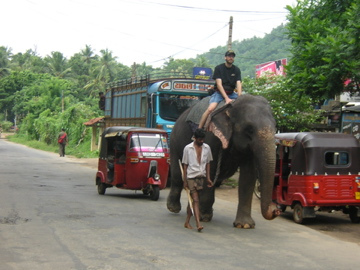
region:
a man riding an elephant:
[163, 46, 278, 239]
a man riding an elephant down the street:
[4, 46, 289, 235]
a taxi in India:
[82, 120, 168, 201]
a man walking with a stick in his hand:
[174, 128, 213, 227]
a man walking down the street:
[49, 123, 85, 167]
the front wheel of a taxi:
[146, 183, 160, 200]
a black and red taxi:
[271, 123, 358, 233]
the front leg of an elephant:
[233, 173, 256, 233]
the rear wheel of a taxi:
[291, 200, 307, 221]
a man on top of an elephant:
[189, 45, 253, 128]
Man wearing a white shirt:
[188, 152, 224, 174]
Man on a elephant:
[204, 51, 241, 100]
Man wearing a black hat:
[220, 43, 240, 63]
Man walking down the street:
[55, 123, 73, 169]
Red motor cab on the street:
[94, 122, 169, 199]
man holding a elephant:
[176, 124, 233, 209]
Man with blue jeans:
[202, 89, 244, 106]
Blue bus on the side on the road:
[92, 72, 201, 141]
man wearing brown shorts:
[182, 174, 212, 196]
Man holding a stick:
[174, 159, 219, 225]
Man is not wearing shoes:
[181, 217, 205, 233]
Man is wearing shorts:
[183, 175, 205, 194]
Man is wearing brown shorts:
[185, 175, 205, 191]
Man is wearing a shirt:
[180, 140, 213, 179]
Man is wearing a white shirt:
[179, 141, 211, 180]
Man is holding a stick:
[174, 152, 195, 217]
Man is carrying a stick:
[177, 158, 196, 217]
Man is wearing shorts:
[204, 88, 246, 103]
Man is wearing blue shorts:
[206, 88, 242, 103]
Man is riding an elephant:
[189, 47, 249, 135]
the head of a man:
[220, 47, 239, 67]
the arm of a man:
[210, 65, 228, 97]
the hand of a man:
[221, 96, 237, 106]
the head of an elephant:
[203, 92, 283, 159]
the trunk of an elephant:
[251, 133, 284, 221]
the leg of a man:
[186, 176, 205, 223]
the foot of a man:
[193, 220, 207, 235]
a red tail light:
[310, 179, 322, 194]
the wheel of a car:
[286, 196, 313, 225]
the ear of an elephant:
[206, 94, 239, 153]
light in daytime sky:
[1, 1, 290, 67]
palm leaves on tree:
[1, 46, 120, 73]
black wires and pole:
[114, 1, 287, 58]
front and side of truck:
[106, 75, 207, 127]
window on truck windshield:
[159, 91, 210, 121]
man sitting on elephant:
[166, 49, 280, 227]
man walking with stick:
[178, 129, 211, 230]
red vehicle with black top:
[275, 132, 356, 220]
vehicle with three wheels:
[96, 125, 170, 199]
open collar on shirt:
[182, 143, 213, 179]